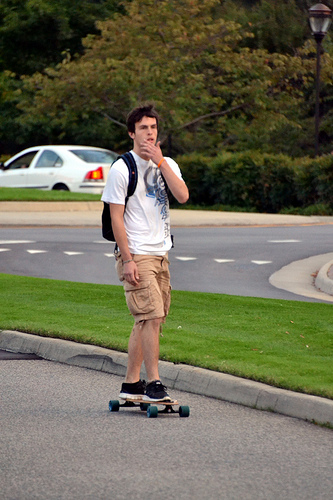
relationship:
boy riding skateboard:
[107, 106, 189, 402] [106, 399, 190, 420]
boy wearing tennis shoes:
[107, 106, 189, 402] [142, 380, 169, 404]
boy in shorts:
[107, 106, 189, 402] [116, 249, 171, 324]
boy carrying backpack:
[107, 106, 189, 402] [100, 151, 138, 241]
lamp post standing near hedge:
[305, 2, 332, 157] [160, 151, 332, 208]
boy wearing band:
[107, 106, 189, 402] [156, 155, 168, 167]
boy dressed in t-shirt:
[107, 106, 189, 402] [101, 158, 184, 255]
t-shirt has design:
[101, 158, 184, 255] [144, 165, 168, 235]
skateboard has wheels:
[106, 399, 190, 420] [148, 407, 158, 416]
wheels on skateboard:
[148, 407, 158, 416] [106, 399, 190, 420]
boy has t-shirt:
[107, 106, 189, 402] [101, 158, 184, 255]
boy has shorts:
[107, 106, 189, 402] [116, 249, 171, 324]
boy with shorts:
[107, 106, 189, 402] [116, 249, 171, 324]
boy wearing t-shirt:
[107, 106, 189, 402] [101, 158, 184, 255]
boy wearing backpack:
[107, 106, 189, 402] [100, 151, 138, 241]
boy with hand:
[107, 106, 189, 402] [140, 142, 165, 165]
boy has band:
[107, 106, 189, 402] [156, 155, 168, 167]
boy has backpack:
[107, 106, 189, 402] [100, 151, 138, 241]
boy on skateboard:
[107, 106, 189, 402] [106, 399, 190, 420]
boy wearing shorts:
[107, 106, 189, 402] [116, 249, 171, 324]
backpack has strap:
[100, 151, 138, 241] [121, 151, 137, 202]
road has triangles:
[1, 220, 332, 299] [251, 256, 271, 268]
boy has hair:
[107, 106, 189, 402] [125, 106, 155, 133]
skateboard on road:
[106, 399, 190, 420] [2, 349, 331, 500]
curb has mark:
[1, 327, 331, 428] [62, 349, 130, 376]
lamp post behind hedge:
[305, 2, 332, 157] [160, 151, 332, 208]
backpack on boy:
[100, 151, 138, 241] [107, 106, 189, 402]